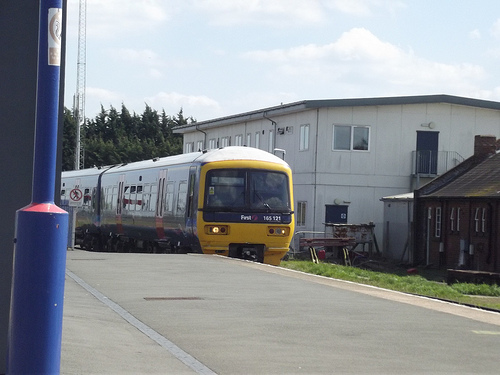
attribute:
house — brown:
[413, 186, 499, 268]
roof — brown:
[413, 149, 499, 198]